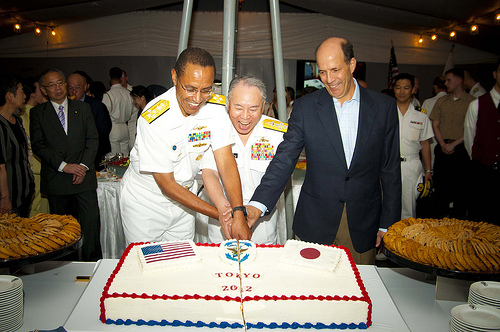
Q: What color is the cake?
A: Red, white and blue.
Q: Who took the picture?
A: A news reporter.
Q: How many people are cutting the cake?
A: Three.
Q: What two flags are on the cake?
A: United States and Tokyo.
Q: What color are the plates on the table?
A: White.